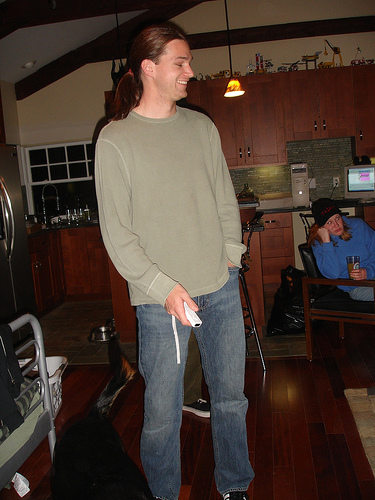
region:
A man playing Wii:
[60, 15, 272, 407]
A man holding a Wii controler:
[81, 29, 265, 394]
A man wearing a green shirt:
[87, 21, 273, 295]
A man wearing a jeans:
[61, 39, 264, 487]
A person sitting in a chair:
[291, 184, 366, 323]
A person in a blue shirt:
[297, 184, 366, 322]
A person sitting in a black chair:
[289, 211, 356, 358]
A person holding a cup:
[312, 199, 365, 310]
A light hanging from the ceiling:
[213, 11, 253, 118]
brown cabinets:
[235, 118, 287, 192]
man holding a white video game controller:
[87, 19, 253, 497]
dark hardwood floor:
[257, 376, 346, 491]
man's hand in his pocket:
[217, 206, 249, 291]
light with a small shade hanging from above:
[212, 0, 247, 105]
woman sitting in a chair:
[296, 187, 373, 365]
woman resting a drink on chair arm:
[324, 246, 373, 286]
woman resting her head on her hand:
[301, 195, 350, 282]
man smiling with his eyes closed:
[160, 41, 201, 106]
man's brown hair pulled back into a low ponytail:
[94, 16, 186, 136]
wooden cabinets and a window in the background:
[21, 63, 317, 326]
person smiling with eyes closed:
[124, 21, 208, 127]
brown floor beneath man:
[270, 414, 342, 498]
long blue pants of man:
[200, 376, 268, 467]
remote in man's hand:
[171, 290, 207, 340]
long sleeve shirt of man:
[108, 94, 229, 259]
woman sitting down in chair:
[280, 192, 367, 310]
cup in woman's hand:
[331, 254, 365, 300]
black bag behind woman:
[269, 268, 304, 337]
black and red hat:
[300, 182, 358, 242]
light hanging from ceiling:
[215, 61, 255, 111]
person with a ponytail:
[99, 20, 200, 133]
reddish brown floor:
[262, 413, 334, 478]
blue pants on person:
[195, 312, 262, 439]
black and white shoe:
[220, 481, 249, 498]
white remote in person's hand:
[166, 295, 204, 342]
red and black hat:
[305, 195, 345, 233]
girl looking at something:
[300, 195, 361, 276]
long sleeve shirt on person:
[97, 131, 235, 276]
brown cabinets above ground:
[259, 74, 332, 137]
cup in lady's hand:
[334, 248, 364, 290]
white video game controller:
[181, 299, 201, 329]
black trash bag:
[263, 264, 316, 337]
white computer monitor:
[344, 162, 374, 200]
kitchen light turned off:
[20, 58, 37, 71]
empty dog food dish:
[88, 314, 116, 342]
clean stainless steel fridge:
[2, 142, 42, 337]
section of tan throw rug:
[344, 384, 374, 470]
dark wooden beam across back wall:
[90, 12, 374, 59]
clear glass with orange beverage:
[345, 254, 361, 279]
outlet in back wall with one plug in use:
[331, 175, 339, 188]